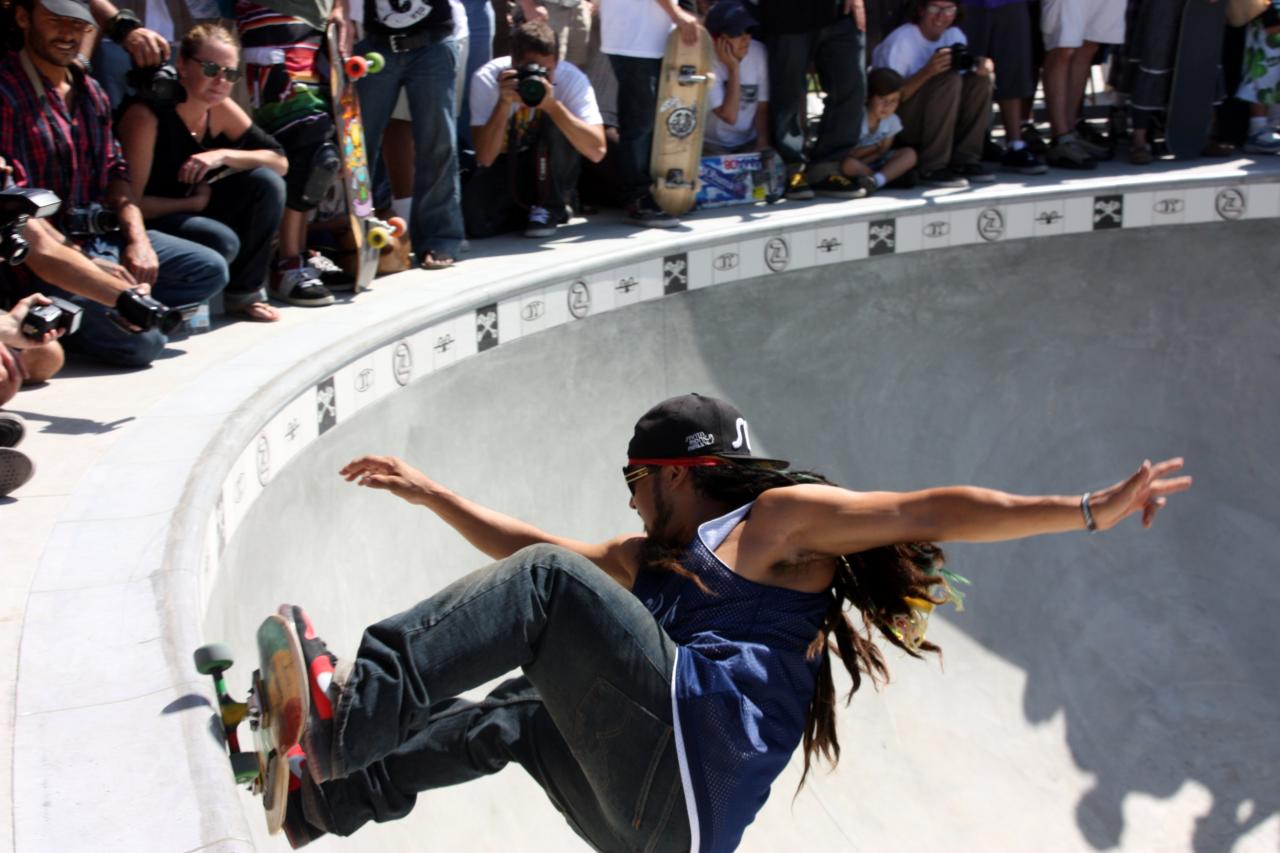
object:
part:
[278, 543, 739, 851]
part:
[622, 392, 789, 542]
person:
[872, 0, 994, 188]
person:
[845, 70, 918, 193]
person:
[768, 0, 866, 199]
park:
[0, 0, 1276, 850]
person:
[705, 10, 768, 209]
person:
[601, 0, 715, 228]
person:
[358, 0, 470, 269]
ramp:
[169, 219, 1280, 852]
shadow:
[683, 245, 1278, 851]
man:
[467, 22, 605, 239]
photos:
[475, 302, 497, 352]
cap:
[626, 392, 787, 469]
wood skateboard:
[650, 21, 715, 217]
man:
[280, 392, 1194, 851]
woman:
[128, 18, 288, 320]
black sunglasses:
[189, 56, 240, 82]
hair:
[691, 465, 971, 781]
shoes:
[280, 605, 337, 848]